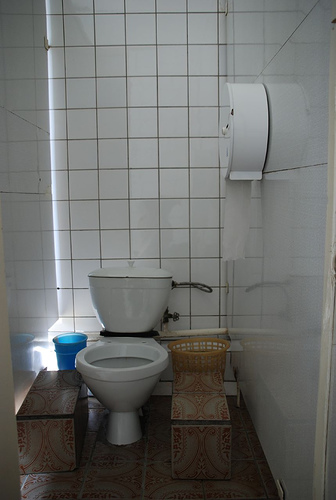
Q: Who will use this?
A: People.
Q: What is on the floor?
A: Toilet.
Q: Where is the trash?
A: Next to the toilet.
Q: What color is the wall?
A: White.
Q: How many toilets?
A: 1.